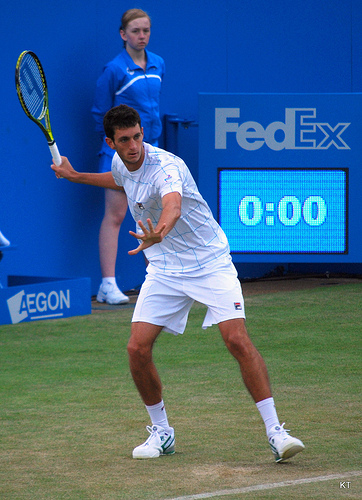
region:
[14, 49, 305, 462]
Man playing tennis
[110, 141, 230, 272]
Shirt on the man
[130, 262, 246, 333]
Shorts on the man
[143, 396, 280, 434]
Long socks on the man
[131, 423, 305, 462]
Shoes on the man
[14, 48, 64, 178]
Racket in the man's hand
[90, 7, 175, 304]
Woman standing behind the man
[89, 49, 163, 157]
Blue jacket on the woman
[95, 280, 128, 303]
Shoe on the woman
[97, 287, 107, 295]
Nike logo on the shoe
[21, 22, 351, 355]
a man playing tennis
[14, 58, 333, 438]
a man on a tennis court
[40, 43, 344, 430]
a man on a grass tennis court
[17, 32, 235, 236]
a man swinging a racket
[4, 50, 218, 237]
a man swinging a tennis racket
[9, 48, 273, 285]
a man holding a racket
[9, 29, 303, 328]
a man holding a tennis racket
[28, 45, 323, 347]
a man wearing a white shirt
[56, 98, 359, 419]
a man wearing white shorts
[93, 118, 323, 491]
a man wearing white socks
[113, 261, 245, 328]
the shorts are white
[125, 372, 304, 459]
the shoes are white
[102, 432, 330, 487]
the shoes are white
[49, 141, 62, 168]
Tennis racket handle is white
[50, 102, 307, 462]
Tennis player is wearing white shorts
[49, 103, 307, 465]
Tennis player wearing white shirt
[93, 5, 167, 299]
Woman wearing blue jacket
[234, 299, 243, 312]
Red, blue and white logo on shorts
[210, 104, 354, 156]
FedEx sign above clock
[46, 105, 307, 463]
Tennis player holding tennis racket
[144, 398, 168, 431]
Long sock is white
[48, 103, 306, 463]
Tennis player extending hand out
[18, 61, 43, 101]
Letter P on tennis racket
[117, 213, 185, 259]
players fingers outstretched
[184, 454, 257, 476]
scorched grass on the court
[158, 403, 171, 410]
label on white socks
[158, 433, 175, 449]
green stripes on side of sneakers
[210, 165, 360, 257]
large clock on the wall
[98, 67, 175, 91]
white line across sports shirt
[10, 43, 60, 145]
gold body on racket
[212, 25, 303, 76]
bright blue wall behind player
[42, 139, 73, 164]
white grip on racket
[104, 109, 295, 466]
player holding his tennis racket